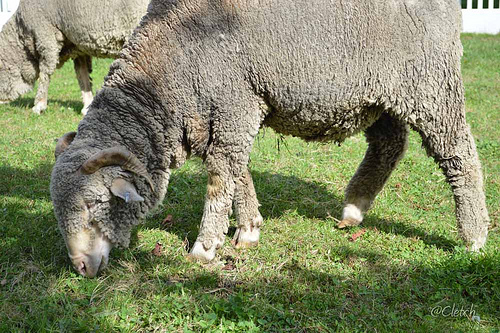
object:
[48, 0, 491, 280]
sheep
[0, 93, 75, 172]
grass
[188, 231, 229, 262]
hoof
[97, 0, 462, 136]
wool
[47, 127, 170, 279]
head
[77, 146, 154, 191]
horn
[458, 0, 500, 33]
wall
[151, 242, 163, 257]
leaf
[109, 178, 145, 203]
ear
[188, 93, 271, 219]
front legs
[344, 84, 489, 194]
back legs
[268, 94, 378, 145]
belly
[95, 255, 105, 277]
mouth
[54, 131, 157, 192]
horns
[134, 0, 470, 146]
body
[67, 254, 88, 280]
snout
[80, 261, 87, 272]
nostril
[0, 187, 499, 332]
field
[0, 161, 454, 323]
shadow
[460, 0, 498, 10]
windows